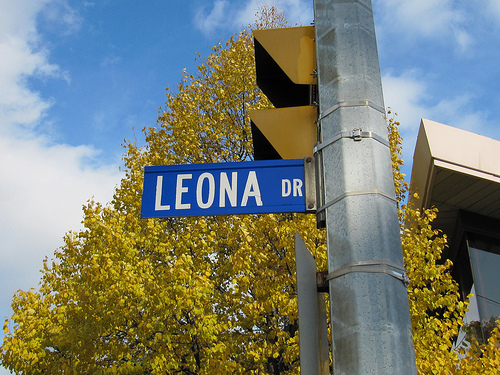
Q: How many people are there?
A: None.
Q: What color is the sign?
A: Blue.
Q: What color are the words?
A: White.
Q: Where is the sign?
A: On the pole.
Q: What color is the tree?
A: Yellow.